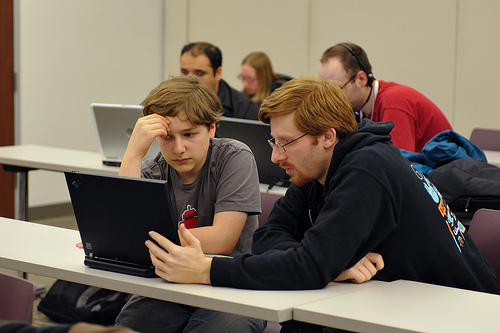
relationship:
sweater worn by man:
[371, 78, 456, 153] [316, 40, 455, 154]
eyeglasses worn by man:
[262, 127, 312, 154] [170, 73, 441, 282]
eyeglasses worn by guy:
[262, 127, 312, 154] [139, 73, 479, 310]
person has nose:
[117, 72, 264, 331] [168, 137, 190, 159]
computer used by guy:
[62, 162, 188, 282] [116, 66, 251, 254]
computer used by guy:
[210, 108, 293, 184] [311, 36, 473, 168]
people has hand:
[206, 73, 499, 331] [138, 218, 215, 284]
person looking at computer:
[117, 72, 264, 331] [64, 170, 232, 279]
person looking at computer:
[117, 72, 264, 331] [63, 167, 181, 277]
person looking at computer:
[144, 92, 464, 295] [56, 159, 206, 289]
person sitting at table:
[117, 72, 264, 331] [0, 210, 498, 330]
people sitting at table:
[206, 73, 499, 331] [0, 210, 498, 330]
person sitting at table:
[321, 46, 457, 155] [3, 137, 299, 203]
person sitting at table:
[154, 44, 284, 159] [3, 137, 299, 203]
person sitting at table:
[239, 49, 284, 102] [459, 127, 499, 165]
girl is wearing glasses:
[238, 54, 284, 114] [239, 69, 256, 83]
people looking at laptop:
[103, 37, 499, 331] [58, 162, 253, 281]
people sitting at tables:
[206, 73, 499, 331] [2, 215, 498, 332]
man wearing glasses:
[141, 76, 498, 331] [259, 128, 312, 152]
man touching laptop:
[141, 76, 498, 331] [60, 162, 192, 281]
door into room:
[2, 3, 17, 213] [3, 2, 494, 332]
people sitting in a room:
[206, 73, 499, 331] [3, 2, 494, 332]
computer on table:
[62, 162, 188, 282] [0, 210, 498, 330]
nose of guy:
[266, 146, 289, 164] [147, 77, 498, 301]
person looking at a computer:
[144, 92, 464, 295] [59, 169, 222, 285]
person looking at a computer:
[321, 46, 457, 155] [210, 108, 293, 184]